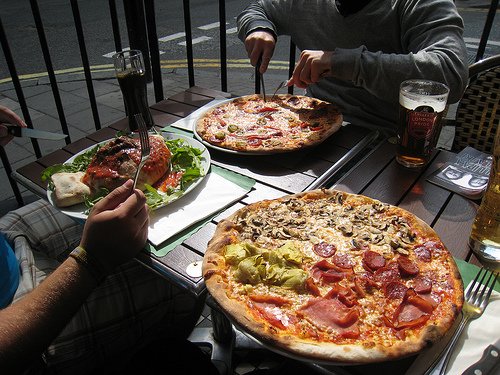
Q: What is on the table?
A: Pizza.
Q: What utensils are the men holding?
A: Fork and knife.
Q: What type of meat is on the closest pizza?
A: Pepperoni, ham.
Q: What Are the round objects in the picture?
A: Pizzas.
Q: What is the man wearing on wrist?
A: A bracelet.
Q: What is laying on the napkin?
A: A fork.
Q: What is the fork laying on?
A: A napkin.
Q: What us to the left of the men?
A: A fence.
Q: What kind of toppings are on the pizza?
A: Meat and veggies.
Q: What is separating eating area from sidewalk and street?
A: Black metal fencing.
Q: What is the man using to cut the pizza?
A: A fork and knife.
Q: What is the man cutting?
A: A pizza.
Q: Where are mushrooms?
A: On half the pizza.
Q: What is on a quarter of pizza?
A: Pepperoni.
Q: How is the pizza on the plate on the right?
A: It is uncut and whole.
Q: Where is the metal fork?
A: On a white napkin.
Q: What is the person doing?
A: Cutting into a pizza.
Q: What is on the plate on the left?
A: A hearty Italian meal.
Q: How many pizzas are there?
A: Two.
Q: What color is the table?
A: Brown.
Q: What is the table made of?
A: Wood.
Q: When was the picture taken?
A: Daytime.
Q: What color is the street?
A: Black.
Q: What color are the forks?
A: Silver.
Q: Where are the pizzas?
A: On the table.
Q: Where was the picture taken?
A: In a restaurant.